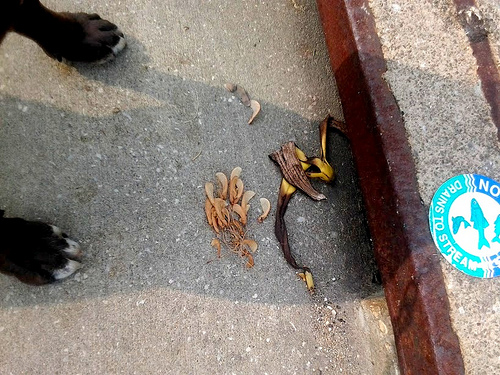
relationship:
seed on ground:
[241, 96, 265, 126] [127, 35, 301, 250]